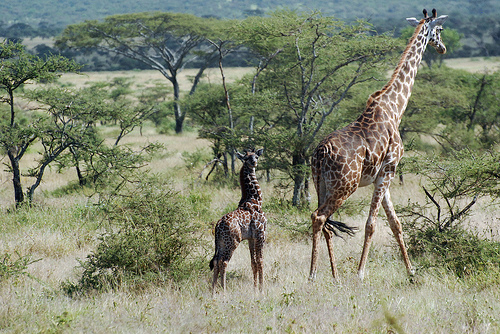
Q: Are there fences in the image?
A: No, there are no fences.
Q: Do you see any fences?
A: No, there are no fences.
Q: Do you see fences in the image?
A: No, there are no fences.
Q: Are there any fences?
A: No, there are no fences.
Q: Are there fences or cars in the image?
A: No, there are no fences or cars.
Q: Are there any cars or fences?
A: No, there are no fences or cars.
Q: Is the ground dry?
A: Yes, the ground is dry.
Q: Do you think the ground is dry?
A: Yes, the ground is dry.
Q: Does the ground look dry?
A: Yes, the ground is dry.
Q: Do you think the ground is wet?
A: No, the ground is dry.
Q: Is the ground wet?
A: No, the ground is dry.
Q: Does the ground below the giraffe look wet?
A: No, the ground is dry.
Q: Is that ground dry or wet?
A: The ground is dry.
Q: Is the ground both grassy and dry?
A: Yes, the ground is grassy and dry.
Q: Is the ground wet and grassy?
A: No, the ground is grassy but dry.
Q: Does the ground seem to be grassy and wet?
A: No, the ground is grassy but dry.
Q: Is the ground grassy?
A: Yes, the ground is grassy.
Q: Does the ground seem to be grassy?
A: Yes, the ground is grassy.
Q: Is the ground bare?
A: No, the ground is grassy.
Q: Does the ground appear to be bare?
A: No, the ground is grassy.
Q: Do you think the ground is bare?
A: No, the ground is grassy.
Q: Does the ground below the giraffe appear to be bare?
A: No, the ground is grassy.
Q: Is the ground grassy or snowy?
A: The ground is grassy.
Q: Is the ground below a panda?
A: No, the ground is below a giraffe.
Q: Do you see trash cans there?
A: No, there are no trash cans.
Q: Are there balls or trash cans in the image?
A: No, there are no trash cans or balls.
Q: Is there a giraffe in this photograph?
A: Yes, there is a giraffe.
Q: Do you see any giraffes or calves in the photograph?
A: Yes, there is a giraffe.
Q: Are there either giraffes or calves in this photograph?
A: Yes, there is a giraffe.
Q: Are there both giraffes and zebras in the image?
A: No, there is a giraffe but no zebras.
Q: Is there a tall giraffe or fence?
A: Yes, there is a tall giraffe.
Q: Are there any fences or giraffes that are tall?
A: Yes, the giraffe is tall.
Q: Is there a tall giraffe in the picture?
A: Yes, there is a tall giraffe.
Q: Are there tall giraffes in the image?
A: Yes, there is a tall giraffe.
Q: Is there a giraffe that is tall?
A: Yes, there is a giraffe that is tall.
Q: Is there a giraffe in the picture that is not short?
A: Yes, there is a tall giraffe.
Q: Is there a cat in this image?
A: No, there are no cats.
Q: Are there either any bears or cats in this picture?
A: No, there are no cats or bears.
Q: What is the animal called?
A: The animal is a giraffe.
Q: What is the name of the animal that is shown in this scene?
A: The animal is a giraffe.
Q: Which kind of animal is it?
A: The animal is a giraffe.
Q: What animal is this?
A: That is a giraffe.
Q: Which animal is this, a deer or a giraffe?
A: That is a giraffe.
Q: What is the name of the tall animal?
A: The animal is a giraffe.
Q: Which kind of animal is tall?
A: The animal is a giraffe.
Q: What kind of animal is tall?
A: The animal is a giraffe.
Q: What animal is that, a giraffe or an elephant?
A: That is a giraffe.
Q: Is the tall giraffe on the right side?
A: Yes, the giraffe is on the right of the image.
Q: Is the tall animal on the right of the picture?
A: Yes, the giraffe is on the right of the image.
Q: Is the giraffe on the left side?
A: No, the giraffe is on the right of the image.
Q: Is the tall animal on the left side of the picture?
A: No, the giraffe is on the right of the image.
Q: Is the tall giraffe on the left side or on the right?
A: The giraffe is on the right of the image.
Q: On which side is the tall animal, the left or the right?
A: The giraffe is on the right of the image.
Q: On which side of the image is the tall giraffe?
A: The giraffe is on the right of the image.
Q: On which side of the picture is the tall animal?
A: The giraffe is on the right of the image.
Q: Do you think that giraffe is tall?
A: Yes, the giraffe is tall.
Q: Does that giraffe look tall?
A: Yes, the giraffe is tall.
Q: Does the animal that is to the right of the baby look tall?
A: Yes, the giraffe is tall.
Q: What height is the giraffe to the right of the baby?
A: The giraffe is tall.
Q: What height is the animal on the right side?
A: The giraffe is tall.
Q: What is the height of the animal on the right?
A: The giraffe is tall.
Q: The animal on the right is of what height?
A: The giraffe is tall.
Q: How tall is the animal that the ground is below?
A: The giraffe is tall.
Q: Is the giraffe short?
A: No, the giraffe is tall.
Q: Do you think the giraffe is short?
A: No, the giraffe is tall.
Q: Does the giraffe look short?
A: No, the giraffe is tall.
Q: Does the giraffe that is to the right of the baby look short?
A: No, the giraffe is tall.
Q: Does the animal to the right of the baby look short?
A: No, the giraffe is tall.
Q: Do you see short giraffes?
A: No, there is a giraffe but it is tall.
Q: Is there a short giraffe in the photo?
A: No, there is a giraffe but it is tall.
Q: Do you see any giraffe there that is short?
A: No, there is a giraffe but it is tall.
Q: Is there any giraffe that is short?
A: No, there is a giraffe but it is tall.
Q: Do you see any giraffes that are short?
A: No, there is a giraffe but it is tall.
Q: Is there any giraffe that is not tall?
A: No, there is a giraffe but it is tall.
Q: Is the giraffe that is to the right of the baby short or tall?
A: The giraffe is tall.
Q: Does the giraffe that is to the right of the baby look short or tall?
A: The giraffe is tall.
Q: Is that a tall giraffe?
A: Yes, that is a tall giraffe.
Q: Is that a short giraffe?
A: No, that is a tall giraffe.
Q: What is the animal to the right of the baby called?
A: The animal is a giraffe.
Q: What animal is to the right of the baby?
A: The animal is a giraffe.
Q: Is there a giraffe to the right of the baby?
A: Yes, there is a giraffe to the right of the baby.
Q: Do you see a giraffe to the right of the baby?
A: Yes, there is a giraffe to the right of the baby.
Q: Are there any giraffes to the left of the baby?
A: No, the giraffe is to the right of the baby.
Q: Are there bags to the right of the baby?
A: No, there is a giraffe to the right of the baby.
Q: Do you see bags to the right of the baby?
A: No, there is a giraffe to the right of the baby.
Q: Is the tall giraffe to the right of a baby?
A: Yes, the giraffe is to the right of a baby.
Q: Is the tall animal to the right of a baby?
A: Yes, the giraffe is to the right of a baby.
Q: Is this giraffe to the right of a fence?
A: No, the giraffe is to the right of a baby.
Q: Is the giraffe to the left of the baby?
A: No, the giraffe is to the right of the baby.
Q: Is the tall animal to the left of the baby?
A: No, the giraffe is to the right of the baby.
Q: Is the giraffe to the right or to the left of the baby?
A: The giraffe is to the right of the baby.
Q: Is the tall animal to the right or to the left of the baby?
A: The giraffe is to the right of the baby.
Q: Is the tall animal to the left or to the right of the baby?
A: The giraffe is to the right of the baby.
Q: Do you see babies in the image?
A: Yes, there is a baby.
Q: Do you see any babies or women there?
A: Yes, there is a baby.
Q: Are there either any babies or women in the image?
A: Yes, there is a baby.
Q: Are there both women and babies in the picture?
A: No, there is a baby but no women.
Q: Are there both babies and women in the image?
A: No, there is a baby but no women.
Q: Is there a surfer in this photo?
A: No, there are no surfers.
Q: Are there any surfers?
A: No, there are no surfers.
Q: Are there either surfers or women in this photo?
A: No, there are no surfers or women.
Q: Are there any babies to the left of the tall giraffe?
A: Yes, there is a baby to the left of the giraffe.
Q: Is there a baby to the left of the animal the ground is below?
A: Yes, there is a baby to the left of the giraffe.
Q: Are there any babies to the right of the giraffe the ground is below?
A: No, the baby is to the left of the giraffe.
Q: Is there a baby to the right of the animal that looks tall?
A: No, the baby is to the left of the giraffe.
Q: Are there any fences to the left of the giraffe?
A: No, there is a baby to the left of the giraffe.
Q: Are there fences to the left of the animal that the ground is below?
A: No, there is a baby to the left of the giraffe.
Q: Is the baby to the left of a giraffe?
A: Yes, the baby is to the left of a giraffe.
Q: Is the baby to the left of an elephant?
A: No, the baby is to the left of a giraffe.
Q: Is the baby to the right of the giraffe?
A: No, the baby is to the left of the giraffe.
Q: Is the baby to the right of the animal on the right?
A: No, the baby is to the left of the giraffe.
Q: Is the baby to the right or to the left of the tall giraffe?
A: The baby is to the left of the giraffe.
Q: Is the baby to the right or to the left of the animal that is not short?
A: The baby is to the left of the giraffe.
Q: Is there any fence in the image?
A: No, there are no fences.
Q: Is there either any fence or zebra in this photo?
A: No, there are no fences or zebras.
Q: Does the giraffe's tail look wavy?
A: Yes, the tail is wavy.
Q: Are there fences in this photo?
A: No, there are no fences.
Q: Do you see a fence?
A: No, there are no fences.